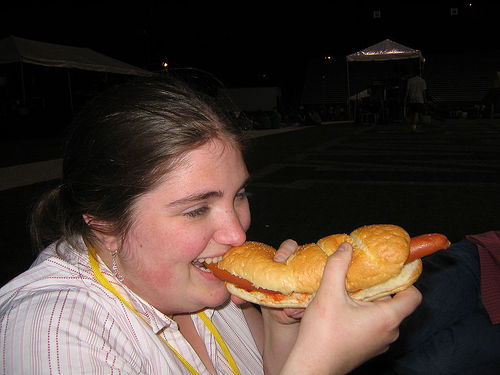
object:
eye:
[174, 199, 213, 223]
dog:
[404, 233, 451, 266]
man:
[404, 69, 427, 135]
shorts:
[410, 97, 425, 113]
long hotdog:
[203, 259, 282, 296]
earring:
[83, 213, 122, 252]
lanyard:
[87, 240, 245, 375]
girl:
[0, 72, 422, 375]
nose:
[211, 199, 246, 246]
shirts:
[0, 233, 264, 375]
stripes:
[0, 290, 124, 374]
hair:
[28, 70, 258, 263]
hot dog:
[198, 233, 451, 295]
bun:
[216, 224, 422, 309]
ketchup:
[254, 286, 314, 304]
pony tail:
[26, 171, 85, 255]